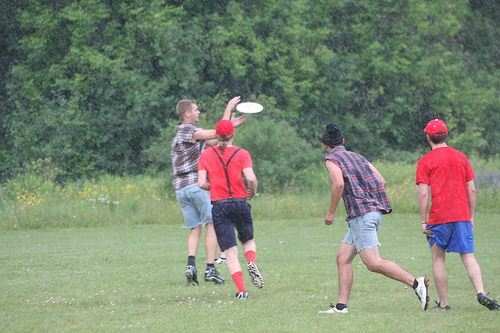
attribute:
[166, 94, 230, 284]
guy — young, playing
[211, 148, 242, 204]
suspenders — black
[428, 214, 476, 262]
shorts — blue, worn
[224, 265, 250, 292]
sock — long, red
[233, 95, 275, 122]
firsbee — white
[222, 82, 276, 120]
frisbee — caught, played, white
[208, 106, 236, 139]
cap — worn, red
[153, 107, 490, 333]
men — playing, young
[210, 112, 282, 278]
man — running, catching, young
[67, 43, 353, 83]
tree — green, dense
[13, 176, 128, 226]
flowers — here, yellow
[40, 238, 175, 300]
grass — green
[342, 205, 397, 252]
jeans — worn, denim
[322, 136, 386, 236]
shirt — flanel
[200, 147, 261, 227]
shirt — red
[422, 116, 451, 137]
hat — here, red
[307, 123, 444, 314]
player — young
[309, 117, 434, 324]
boy — catching